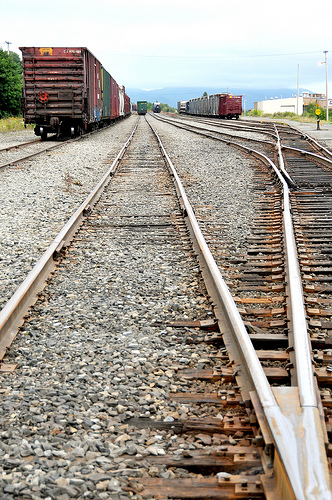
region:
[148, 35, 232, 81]
this is the sky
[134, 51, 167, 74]
the sky is bright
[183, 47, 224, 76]
the sky is blue in color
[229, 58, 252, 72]
the sky has clouds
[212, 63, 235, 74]
the clouds are white in color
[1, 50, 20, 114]
this is a tree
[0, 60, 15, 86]
the leaves are green in color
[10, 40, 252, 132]
these are some trains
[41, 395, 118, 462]
these are some pebbles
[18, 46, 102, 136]
The last rusty red train car on the far left.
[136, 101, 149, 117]
A single green train car far up the tracks.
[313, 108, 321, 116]
A round yellow sign.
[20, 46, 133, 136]
A long left side section of train cars going down the tracks.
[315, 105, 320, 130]
Small brown pole holding a yellow round sign.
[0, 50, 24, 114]
Green tree to the left of the left side train cars.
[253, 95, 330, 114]
A long white building over by a yellow sign.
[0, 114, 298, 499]
The longest straightest tracks going to a green car.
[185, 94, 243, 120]
A long strip of train cars that are grey and the last one red.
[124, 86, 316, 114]
Blue tinted land way in the distance.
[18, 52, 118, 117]
this is the train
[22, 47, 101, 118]
the train is red in color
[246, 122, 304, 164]
these are the rails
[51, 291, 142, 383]
these are small stones in the middle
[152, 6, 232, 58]
this is the sky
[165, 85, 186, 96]
this is the mountain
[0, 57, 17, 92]
this is a tree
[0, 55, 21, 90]
the tree is leafy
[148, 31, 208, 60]
the sky is clear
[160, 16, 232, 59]
the sky is white in color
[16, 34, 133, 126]
train on a track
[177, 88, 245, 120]
train on a track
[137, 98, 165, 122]
trains on the tracks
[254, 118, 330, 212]
tracks for trains to travel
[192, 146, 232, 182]
gravel on the tracks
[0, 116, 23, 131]
grass near the tracks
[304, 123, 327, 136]
concrete near the track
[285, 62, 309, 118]
pole near the track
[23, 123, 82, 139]
wheels on a train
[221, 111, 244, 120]
wheels on a train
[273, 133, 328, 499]
steel railroad tracks at a train yard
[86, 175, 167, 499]
gravel between the steel tracks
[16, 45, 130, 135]
railroad container cars at the train yard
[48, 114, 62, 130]
railroad train car coupler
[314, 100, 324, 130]
a railroad train traffic signal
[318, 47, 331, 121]
a street light and pole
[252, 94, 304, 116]
an industrial warehouse across from the train yard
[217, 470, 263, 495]
steel bolts securing the railroad ties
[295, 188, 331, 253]
wooden railroad ties between the tracks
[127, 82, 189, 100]
large mountains in the distance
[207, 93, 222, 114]
A train car on a track.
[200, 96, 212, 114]
A train car on a track.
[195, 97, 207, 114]
A train car on a track.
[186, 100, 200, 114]
A train car on a track.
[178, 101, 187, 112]
A train car on a track.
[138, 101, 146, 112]
A train car on a track.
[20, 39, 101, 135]
A train car on a track.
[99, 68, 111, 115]
A train car on a track.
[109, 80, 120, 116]
A train car on a track.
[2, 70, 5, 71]
A green leaf on a plant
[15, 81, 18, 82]
A green leaf on a plant